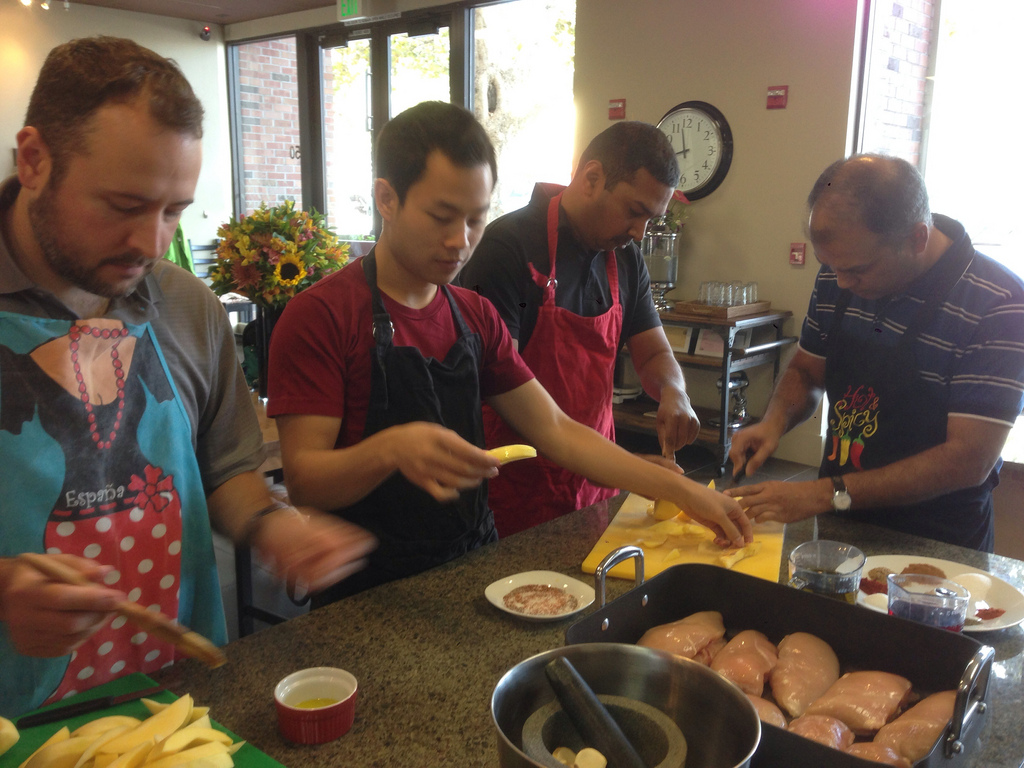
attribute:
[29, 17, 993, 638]
men — four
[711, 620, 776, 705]
piece — raw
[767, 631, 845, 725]
piece — raw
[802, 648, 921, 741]
meat — raw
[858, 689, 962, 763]
meat — raw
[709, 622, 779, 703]
meat — raw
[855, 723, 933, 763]
meat — raw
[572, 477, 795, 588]
board — yellow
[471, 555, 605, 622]
plate — small, white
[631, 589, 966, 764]
chicken — raw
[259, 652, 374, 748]
cup — small, red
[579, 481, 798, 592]
cutting board — yellow, rectangular